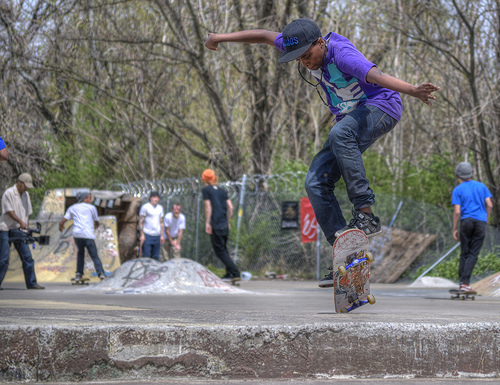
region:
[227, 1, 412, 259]
this is a man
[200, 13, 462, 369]
skateboarder is doing a trick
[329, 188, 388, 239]
man wearing black shoes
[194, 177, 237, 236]
man wearing black shirt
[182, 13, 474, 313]
man on a skateboard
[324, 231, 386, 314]
skateboard is tilted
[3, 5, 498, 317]
a group of skateboarders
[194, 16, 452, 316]
man doing a skateboard trick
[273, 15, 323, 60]
blue and black hat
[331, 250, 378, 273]
a set of wheels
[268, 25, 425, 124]
purple, blue, and white shirt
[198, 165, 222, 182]
orange hat on the head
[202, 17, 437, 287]
A teenager skate boarding and performing a trick in a skate park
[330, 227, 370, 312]
A skateboard on which a trick is being performed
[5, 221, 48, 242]
A professional video recorder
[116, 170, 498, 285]
A broken down chain link fence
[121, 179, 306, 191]
Barbed wire on the top of a fence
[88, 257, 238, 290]
Two raised mounds at a skate park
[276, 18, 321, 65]
A black fitted cap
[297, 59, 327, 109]
A bead necklace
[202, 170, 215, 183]
An orange beanie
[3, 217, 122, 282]
A wooden skate boarding ramp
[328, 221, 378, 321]
it is skating board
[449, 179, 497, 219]
man wearing blue color shirt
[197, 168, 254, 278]
man wearing orange color cap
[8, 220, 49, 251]
it is video camera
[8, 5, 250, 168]
it is a forest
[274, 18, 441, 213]
man wearing black color cap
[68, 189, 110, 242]
man wearing white color shirt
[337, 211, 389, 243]
man wearing black color shoe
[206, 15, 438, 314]
A boy on a skate board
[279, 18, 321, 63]
A back baseball hat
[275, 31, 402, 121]
A purple short sleeved shirt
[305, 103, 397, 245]
A pair of blue jeans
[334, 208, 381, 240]
A black sneaker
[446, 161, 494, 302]
A skater in a blue shirt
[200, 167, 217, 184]
An orange hat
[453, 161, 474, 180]
A grey hat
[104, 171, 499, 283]
A silver metal fence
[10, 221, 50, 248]
A black video camera